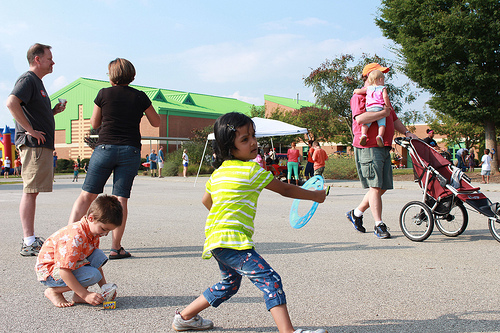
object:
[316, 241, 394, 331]
pavement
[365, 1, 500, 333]
right side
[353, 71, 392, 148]
girl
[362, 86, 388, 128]
pink and blue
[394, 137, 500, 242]
stroller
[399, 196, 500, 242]
3 wheels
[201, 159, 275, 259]
shirt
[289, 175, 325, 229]
frisbee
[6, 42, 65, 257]
man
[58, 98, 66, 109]
cup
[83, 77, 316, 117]
roof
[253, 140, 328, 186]
people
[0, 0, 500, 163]
background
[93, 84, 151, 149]
shirt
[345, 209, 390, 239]
shoes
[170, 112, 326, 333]
girl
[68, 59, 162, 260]
woman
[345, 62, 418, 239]
man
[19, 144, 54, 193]
shorts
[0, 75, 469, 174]
building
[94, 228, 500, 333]
shadows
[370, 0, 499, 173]
trees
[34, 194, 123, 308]
child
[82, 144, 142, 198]
shorts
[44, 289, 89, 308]
bare feet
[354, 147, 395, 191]
pants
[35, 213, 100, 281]
shirt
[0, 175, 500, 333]
ground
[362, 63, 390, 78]
cap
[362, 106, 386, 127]
blue pants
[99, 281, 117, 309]
candy